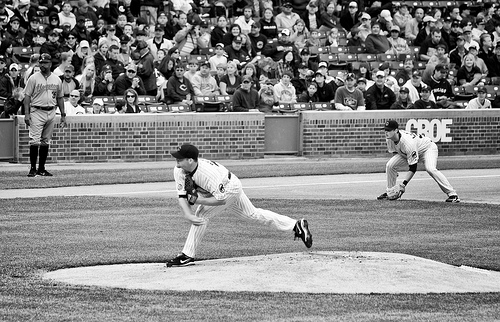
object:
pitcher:
[160, 139, 313, 270]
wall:
[98, 123, 166, 159]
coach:
[21, 43, 70, 177]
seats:
[317, 51, 349, 66]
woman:
[118, 88, 142, 111]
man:
[334, 71, 366, 110]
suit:
[173, 159, 295, 253]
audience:
[115, 61, 143, 94]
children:
[185, 61, 199, 77]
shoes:
[289, 216, 316, 249]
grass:
[55, 203, 130, 237]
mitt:
[385, 186, 405, 200]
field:
[0, 153, 500, 317]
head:
[342, 70, 358, 89]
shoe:
[163, 250, 196, 269]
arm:
[170, 168, 206, 225]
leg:
[227, 179, 312, 267]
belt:
[197, 170, 240, 197]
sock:
[27, 146, 40, 166]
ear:
[183, 156, 198, 166]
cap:
[163, 144, 204, 160]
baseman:
[375, 117, 463, 201]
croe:
[404, 119, 457, 145]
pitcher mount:
[42, 251, 499, 295]